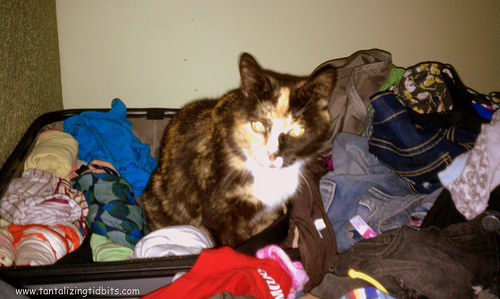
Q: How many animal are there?
A: One.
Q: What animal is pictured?
A: A cat.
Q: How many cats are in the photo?
A: One.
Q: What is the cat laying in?
A: A suitcase.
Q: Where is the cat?
A: In a suitcase.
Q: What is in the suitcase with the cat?
A: Clothes.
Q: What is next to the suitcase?
A: Clothes.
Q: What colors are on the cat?
A: Orange, brown and white.